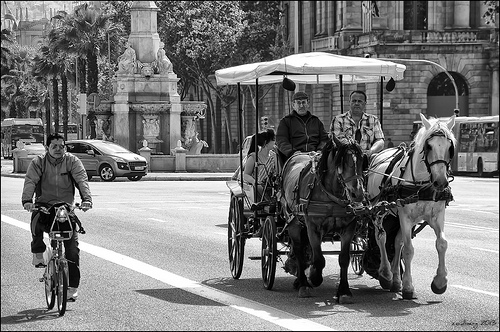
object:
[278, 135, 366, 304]
horse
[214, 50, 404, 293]
carriage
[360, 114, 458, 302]
horse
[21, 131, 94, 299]
person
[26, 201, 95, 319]
bike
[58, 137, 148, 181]
car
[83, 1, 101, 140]
trees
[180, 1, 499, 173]
building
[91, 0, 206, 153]
statue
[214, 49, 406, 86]
canopy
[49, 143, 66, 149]
glasses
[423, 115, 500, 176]
bus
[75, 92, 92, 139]
light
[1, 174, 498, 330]
road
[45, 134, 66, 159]
head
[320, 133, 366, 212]
head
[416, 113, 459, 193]
head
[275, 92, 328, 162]
person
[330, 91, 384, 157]
person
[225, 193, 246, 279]
wheel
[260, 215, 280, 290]
wheel